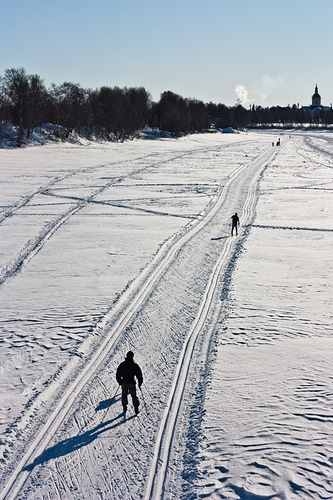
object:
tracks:
[142, 135, 290, 499]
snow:
[0, 128, 332, 498]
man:
[114, 349, 142, 420]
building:
[300, 83, 332, 125]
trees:
[0, 65, 298, 149]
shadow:
[20, 409, 136, 472]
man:
[228, 212, 240, 236]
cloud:
[231, 84, 251, 110]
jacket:
[113, 357, 144, 391]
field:
[0, 130, 332, 499]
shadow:
[209, 233, 229, 241]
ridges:
[39, 188, 332, 232]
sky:
[0, 0, 332, 110]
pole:
[137, 380, 147, 407]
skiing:
[98, 348, 151, 433]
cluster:
[0, 68, 252, 150]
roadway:
[0, 128, 332, 499]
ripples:
[0, 137, 257, 288]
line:
[41, 143, 120, 152]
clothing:
[229, 215, 240, 226]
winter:
[0, 0, 332, 499]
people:
[273, 137, 280, 149]